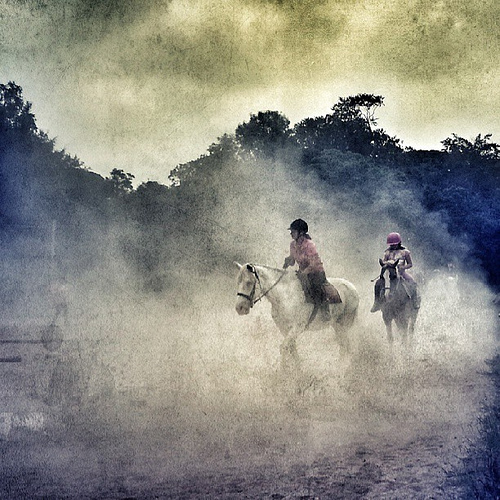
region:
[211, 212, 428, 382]
two people riding on horses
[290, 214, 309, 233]
black horse riding helmet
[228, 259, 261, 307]
white head of horse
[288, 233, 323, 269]
pink shirt of person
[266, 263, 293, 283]
black reigns of horse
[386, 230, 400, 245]
pink horse riding helmet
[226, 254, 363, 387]
large white horse walking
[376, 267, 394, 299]
white stripe down horse face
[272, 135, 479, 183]
trees in back of mist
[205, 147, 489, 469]
two horses walking together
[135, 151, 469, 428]
fog is around the horses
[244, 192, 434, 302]
the girls are wearing helmets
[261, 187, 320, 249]
the helmet is black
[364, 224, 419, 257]
the helmet is red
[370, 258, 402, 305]
the horse has white on its face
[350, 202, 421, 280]
the girl is looking down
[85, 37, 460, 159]
the sky is overcast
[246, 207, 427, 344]
two people riding some horses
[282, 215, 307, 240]
the head of a woman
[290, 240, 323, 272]
the torso of a woman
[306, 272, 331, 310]
the leg of a woman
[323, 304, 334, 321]
the shoe of a woman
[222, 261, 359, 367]
a large white racehorse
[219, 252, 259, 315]
the head of a white horse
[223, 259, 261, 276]
the ear of a white horse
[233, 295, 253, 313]
the nose of a white horse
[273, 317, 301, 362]
the legs of a white horse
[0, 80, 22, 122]
top of tree in forest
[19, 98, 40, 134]
top of tree in forest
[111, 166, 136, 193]
top of tree in forest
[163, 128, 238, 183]
top of tree in forest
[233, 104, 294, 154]
top of tree in forest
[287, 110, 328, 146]
top of tree in forest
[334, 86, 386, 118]
top of tree in forest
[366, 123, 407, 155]
top of tree in forest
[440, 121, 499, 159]
top of tree in forest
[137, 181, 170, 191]
top of tree in forest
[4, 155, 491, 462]
Fog is in the air.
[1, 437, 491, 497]
The surface is gray.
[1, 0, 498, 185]
The sky is mottled.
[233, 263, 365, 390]
A horse is white.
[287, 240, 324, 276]
The shirt is pink.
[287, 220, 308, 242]
A head is wearing a helmet.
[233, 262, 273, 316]
A bridle is on a horse.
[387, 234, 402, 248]
The helmet is pink.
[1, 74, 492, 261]
The trees have leaves.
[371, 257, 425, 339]
A horse is dark and light.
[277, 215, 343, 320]
A person riding on the horse.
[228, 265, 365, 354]
The horse is white.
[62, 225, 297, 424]
Dust in the air.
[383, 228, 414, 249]
The helmet on top of the person head.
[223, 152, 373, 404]
The girl is on the horse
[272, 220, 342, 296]
The girl is wearing a helmet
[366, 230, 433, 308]
The girl is wearing a helmet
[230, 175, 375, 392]
The girl is riding a horse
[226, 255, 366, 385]
The horse is white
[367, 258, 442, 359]
The horse is brown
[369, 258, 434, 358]
The horse has a white nose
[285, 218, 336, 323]
girl on a horse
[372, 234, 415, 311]
girl on a horse